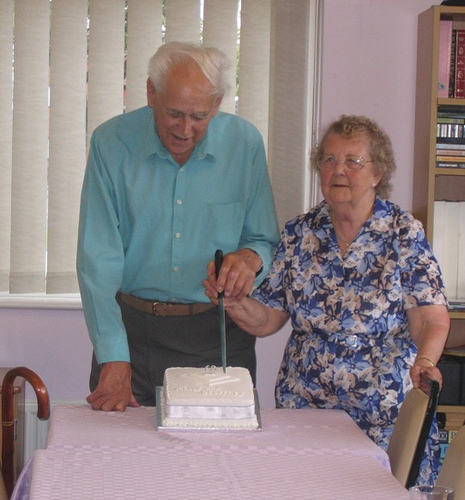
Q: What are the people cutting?
A: Cake.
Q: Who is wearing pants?
A: The man.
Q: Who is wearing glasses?
A: The woman.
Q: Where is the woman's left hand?
A: On the chair.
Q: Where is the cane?
A: Left of the table.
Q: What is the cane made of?
A: Wood.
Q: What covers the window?
A: Blinds.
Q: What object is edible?
A: The cake.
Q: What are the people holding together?
A: Knife.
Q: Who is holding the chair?
A: Woman with glasses.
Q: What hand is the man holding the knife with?
A: Left.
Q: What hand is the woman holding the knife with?
A: Right.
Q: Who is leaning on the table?
A: Man holding the knife.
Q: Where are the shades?
A: Over window.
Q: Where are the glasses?
A: On woman's face.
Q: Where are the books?
A: Bookshelf.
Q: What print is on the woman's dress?
A: Floral.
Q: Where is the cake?
A: On table.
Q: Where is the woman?
A: Standing next to the man.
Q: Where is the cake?
A: On the table.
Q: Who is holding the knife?
A: The man and woman.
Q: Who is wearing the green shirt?
A: The man on the left.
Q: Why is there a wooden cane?
A: To help the man walk.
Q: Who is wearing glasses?
A: The woman in the dress.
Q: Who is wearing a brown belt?
A: The man in the green shirt.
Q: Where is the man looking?
A: At the cake.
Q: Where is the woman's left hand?
A: On the back of a chair.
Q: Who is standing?
A: The man and woman.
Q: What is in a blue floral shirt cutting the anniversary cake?
A: The woman.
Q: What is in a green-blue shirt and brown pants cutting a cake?
A: The older gentleman.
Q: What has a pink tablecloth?
A: The table.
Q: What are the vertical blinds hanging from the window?
A: Off-white.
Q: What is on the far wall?
A: The bookcase.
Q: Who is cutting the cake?
A: The couple.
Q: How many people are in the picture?
A: Two.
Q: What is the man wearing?
A: Shirt, slacks and belt.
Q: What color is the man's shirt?
A: Blue.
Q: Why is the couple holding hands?
A: To cut the cake.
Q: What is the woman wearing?
A: Blue floral dress.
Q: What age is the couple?
A: Elderly.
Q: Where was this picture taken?
A: At the table.